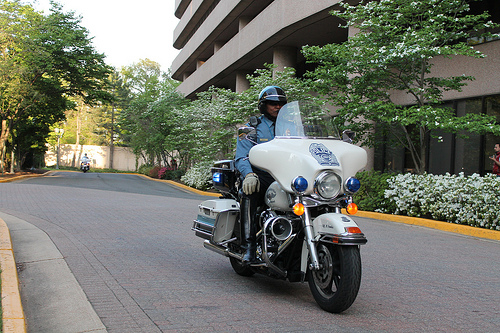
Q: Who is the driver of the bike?
A: Police officer.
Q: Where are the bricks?
A: On road.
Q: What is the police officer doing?
A: Riding a bike.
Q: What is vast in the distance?
A: Trees.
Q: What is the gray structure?
A: A building.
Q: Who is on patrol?
A: Police officer.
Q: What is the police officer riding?
A: Motorbike.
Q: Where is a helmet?
A: On officer's head.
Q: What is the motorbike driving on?
A: Road.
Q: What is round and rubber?
A: Motorcycle tires.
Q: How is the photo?
A: Clear.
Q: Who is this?
A: Officer.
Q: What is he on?
A: Motorcycle.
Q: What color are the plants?
A: Green.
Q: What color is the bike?
A: White.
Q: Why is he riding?
A: Patrolling.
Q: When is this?
A: Daytime.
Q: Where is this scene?
A: On the road.